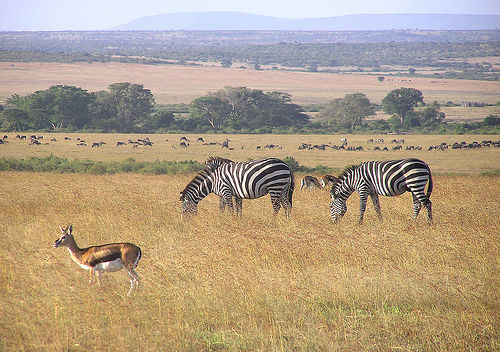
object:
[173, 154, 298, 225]
zebra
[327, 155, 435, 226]
zebra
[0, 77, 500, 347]
bush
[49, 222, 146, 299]
antelope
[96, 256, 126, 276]
belly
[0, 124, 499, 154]
herd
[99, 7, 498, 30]
mountain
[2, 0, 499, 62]
horizon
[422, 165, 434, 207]
tail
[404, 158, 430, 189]
back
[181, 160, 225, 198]
mane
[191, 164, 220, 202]
neck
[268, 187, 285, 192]
stripes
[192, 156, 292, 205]
torso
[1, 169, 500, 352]
grass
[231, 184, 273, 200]
stomach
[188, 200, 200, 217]
jaw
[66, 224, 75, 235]
ear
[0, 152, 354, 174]
bush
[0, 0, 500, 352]
photo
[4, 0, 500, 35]
sky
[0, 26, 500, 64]
savannah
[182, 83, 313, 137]
tree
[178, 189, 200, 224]
head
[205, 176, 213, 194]
stripes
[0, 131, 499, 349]
field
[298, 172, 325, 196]
deer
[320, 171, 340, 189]
animal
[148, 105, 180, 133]
bushes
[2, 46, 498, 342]
pasture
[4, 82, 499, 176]
middle